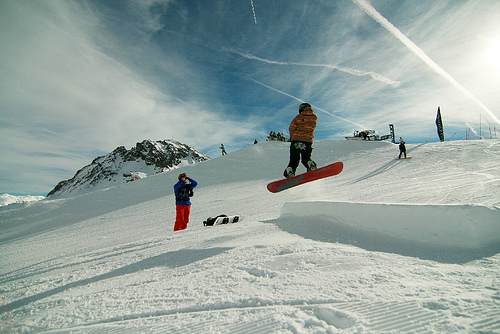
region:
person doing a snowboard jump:
[260, 90, 355, 199]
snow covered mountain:
[55, 118, 215, 198]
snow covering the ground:
[151, 249, 296, 321]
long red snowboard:
[267, 165, 366, 205]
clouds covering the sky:
[48, 38, 338, 128]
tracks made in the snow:
[136, 283, 356, 325]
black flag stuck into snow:
[428, 98, 458, 148]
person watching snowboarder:
[159, 165, 204, 235]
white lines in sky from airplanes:
[230, 0, 391, 112]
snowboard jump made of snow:
[258, 185, 486, 248]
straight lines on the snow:
[330, 292, 462, 325]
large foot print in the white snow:
[283, 293, 356, 326]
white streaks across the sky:
[195, 37, 402, 104]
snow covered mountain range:
[74, 134, 200, 173]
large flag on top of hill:
[425, 105, 447, 147]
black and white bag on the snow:
[200, 207, 262, 228]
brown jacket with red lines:
[267, 104, 332, 154]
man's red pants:
[153, 187, 207, 235]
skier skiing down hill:
[210, 135, 248, 171]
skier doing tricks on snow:
[245, 82, 370, 202]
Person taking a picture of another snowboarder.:
[167, 166, 204, 236]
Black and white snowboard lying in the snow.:
[205, 209, 247, 231]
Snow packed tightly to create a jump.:
[276, 194, 498, 252]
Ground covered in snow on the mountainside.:
[37, 236, 465, 331]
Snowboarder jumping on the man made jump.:
[256, 97, 358, 195]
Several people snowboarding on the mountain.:
[116, 107, 442, 239]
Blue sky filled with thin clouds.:
[26, 11, 401, 83]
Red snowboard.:
[265, 159, 350, 201]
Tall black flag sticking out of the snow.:
[432, 97, 451, 146]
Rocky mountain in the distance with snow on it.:
[56, 133, 206, 189]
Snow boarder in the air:
[259, 78, 387, 217]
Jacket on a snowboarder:
[275, 94, 321, 145]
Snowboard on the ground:
[201, 199, 244, 239]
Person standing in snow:
[161, 159, 211, 236]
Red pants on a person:
[166, 194, 203, 229]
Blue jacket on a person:
[168, 168, 206, 220]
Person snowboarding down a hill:
[391, 131, 425, 168]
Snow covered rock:
[89, 119, 218, 185]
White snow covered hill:
[31, 176, 316, 332]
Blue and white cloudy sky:
[31, 58, 273, 126]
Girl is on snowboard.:
[248, 91, 355, 198]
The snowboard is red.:
[247, 155, 361, 195]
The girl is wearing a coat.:
[278, 103, 325, 146]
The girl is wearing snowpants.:
[277, 137, 322, 184]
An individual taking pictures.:
[167, 165, 203, 235]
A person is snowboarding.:
[383, 132, 418, 163]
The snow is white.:
[0, 129, 499, 332]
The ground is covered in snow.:
[1, 131, 498, 332]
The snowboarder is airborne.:
[266, 91, 346, 202]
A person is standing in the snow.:
[172, 162, 204, 241]